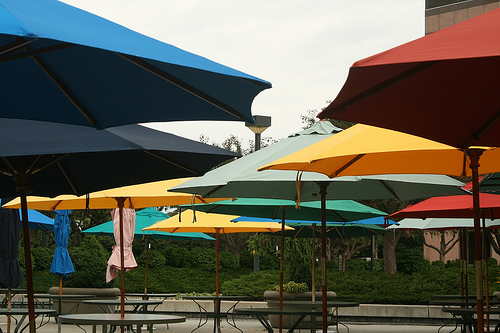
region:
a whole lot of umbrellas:
[3, 13, 489, 292]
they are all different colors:
[28, 15, 487, 269]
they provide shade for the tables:
[58, 275, 189, 329]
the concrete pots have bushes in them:
[259, 273, 346, 328]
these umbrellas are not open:
[50, 206, 137, 280]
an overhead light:
[242, 110, 273, 145]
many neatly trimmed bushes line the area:
[20, 235, 246, 280]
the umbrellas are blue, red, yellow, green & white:
[28, 12, 490, 233]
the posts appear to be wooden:
[313, 187, 343, 332]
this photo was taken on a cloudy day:
[11, 0, 497, 331]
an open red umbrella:
[317, 2, 499, 148]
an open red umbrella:
[382, 193, 497, 218]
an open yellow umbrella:
[260, 120, 499, 178]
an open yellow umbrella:
[0, 177, 237, 211]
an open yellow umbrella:
[141, 207, 293, 232]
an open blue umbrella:
[0, 0, 271, 130]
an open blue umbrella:
[227, 212, 399, 226]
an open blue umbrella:
[80, 208, 217, 242]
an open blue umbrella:
[19, 207, 57, 227]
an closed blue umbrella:
[46, 208, 74, 275]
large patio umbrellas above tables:
[3, 3, 497, 323]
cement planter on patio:
[261, 276, 336, 331]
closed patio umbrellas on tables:
[42, 208, 156, 283]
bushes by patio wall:
[133, 242, 498, 305]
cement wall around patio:
[126, 288, 488, 331]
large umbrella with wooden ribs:
[1, 110, 248, 327]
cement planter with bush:
[48, 253, 139, 330]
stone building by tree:
[358, 12, 495, 270]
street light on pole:
[238, 95, 275, 299]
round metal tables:
[180, 280, 368, 331]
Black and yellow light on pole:
[246, 115, 270, 150]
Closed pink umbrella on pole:
[106, 209, 138, 281]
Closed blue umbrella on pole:
[52, 212, 72, 274]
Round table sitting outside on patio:
[56, 313, 186, 331]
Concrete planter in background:
[263, 289, 338, 327]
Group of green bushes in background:
[138, 250, 238, 270]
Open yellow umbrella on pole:
[256, 122, 498, 177]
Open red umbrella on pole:
[382, 193, 499, 218]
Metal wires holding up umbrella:
[1, 150, 234, 197]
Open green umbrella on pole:
[178, 199, 391, 220]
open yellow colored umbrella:
[304, 135, 409, 178]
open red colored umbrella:
[372, 53, 499, 170]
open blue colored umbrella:
[55, 14, 146, 86]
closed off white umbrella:
[111, 199, 141, 273]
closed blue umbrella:
[54, 195, 75, 281]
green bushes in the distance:
[150, 241, 402, 298]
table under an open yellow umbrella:
[54, 299, 193, 331]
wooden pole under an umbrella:
[211, 231, 229, 328]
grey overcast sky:
[252, 11, 322, 66]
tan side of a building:
[419, 11, 485, 29]